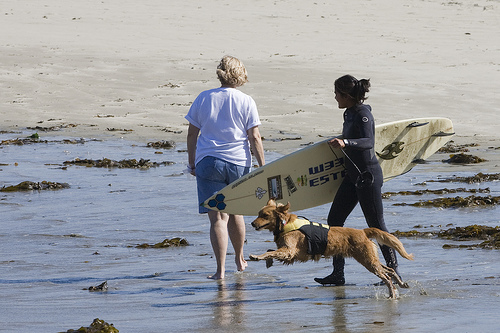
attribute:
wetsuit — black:
[298, 85, 400, 286]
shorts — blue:
[189, 150, 253, 214]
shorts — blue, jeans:
[183, 157, 250, 219]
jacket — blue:
[297, 222, 327, 257]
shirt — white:
[186, 88, 261, 167]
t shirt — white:
[158, 77, 268, 164]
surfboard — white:
[202, 125, 449, 210]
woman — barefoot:
[186, 55, 267, 276]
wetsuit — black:
[340, 110, 378, 175]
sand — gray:
[0, 2, 499, 143]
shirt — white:
[187, 82, 257, 165]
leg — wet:
[358, 246, 398, 296]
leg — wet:
[378, 259, 412, 287]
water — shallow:
[81, 143, 183, 248]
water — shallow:
[2, 131, 499, 331]